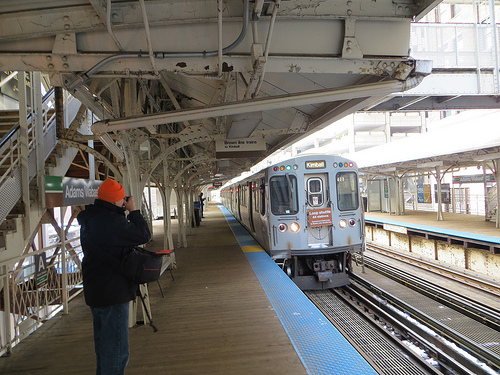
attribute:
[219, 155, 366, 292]
train — blue, gray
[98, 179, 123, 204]
beanie — red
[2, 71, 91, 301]
stairs — metal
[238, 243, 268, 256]
paint — yellow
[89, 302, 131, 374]
jeans — blue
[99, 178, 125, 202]
cap — orange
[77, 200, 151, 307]
coat — black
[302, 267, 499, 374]
tracks — metal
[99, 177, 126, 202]
hat — orange, bright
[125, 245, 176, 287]
bag — black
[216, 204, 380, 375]
edge — blue, aqua colored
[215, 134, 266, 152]
sign — white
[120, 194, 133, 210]
camera — black